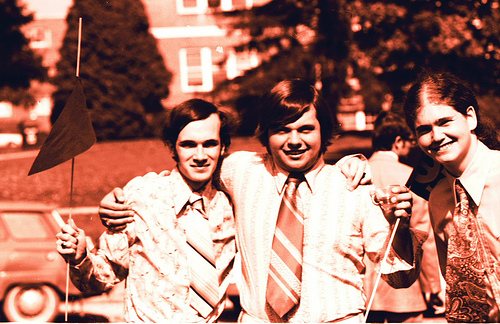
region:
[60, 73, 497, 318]
The three men looking at the camera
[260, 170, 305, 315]
The tie of the middle man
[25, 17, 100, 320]
The flag held by the man on the left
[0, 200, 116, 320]
The back end of the car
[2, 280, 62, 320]
The tire on the car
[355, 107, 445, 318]
The man facing away from the camera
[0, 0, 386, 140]
The building in the background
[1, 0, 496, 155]
The trees in front of the building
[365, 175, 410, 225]
The cup in the left hand of the middle man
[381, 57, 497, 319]
The man on right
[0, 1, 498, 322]
photo is either from the late 1960s or a remarkable simulation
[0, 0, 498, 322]
photo is sepiatoned to the point of its being rusty red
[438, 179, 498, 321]
enormous paisley tie on guy to left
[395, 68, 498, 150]
tied back hair w/ straight centre part on guy to left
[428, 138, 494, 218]
collar w/ fairly wide/long collar on guy to left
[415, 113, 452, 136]
squinty eyes from sunlight on guy to left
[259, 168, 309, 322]
striped tie on middle guy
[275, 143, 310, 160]
wide smile on middle guy [who looks kind of like jan wenner]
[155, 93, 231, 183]
marvellous 1960s hairdo with left side part+a few flyaways on guy @ right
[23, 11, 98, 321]
guy @ right holds pointy black flag [why i dont know]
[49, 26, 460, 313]
a group of men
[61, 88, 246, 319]
a man holding a weird flag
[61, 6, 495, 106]
trees in the background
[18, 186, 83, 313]
a car parked on the side of the road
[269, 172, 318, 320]
a mans tie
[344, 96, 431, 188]
a man behind the scene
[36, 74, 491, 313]
three friends having fun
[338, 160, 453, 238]
the man holding some sort of cup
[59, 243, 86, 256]
a ring on the guys finger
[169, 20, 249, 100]
windows of the building in the back ground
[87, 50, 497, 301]
3 men pictured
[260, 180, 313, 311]
the man has a tie on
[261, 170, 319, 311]
the tie is striped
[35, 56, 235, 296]
man to far left is holding a flag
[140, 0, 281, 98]
building is behind trees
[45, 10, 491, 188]
trees are behind the men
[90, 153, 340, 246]
man's arm is around man to left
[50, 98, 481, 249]
the men are smiling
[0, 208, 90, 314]
car is parked behind men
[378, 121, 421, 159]
man is wearing glasses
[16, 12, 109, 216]
triangular flag on a stick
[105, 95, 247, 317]
man with shaggy hair in an old tie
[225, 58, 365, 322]
man with shaggy hair and a tie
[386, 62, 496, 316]
person with long hair and a wide tie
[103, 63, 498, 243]
trio of friends wearing ties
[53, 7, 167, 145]
very tall evergreen tree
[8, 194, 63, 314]
back end of an old station wagon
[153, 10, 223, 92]
old brick building with windows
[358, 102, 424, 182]
man with brown hair and glasses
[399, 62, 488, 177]
smiling man with long brow hair